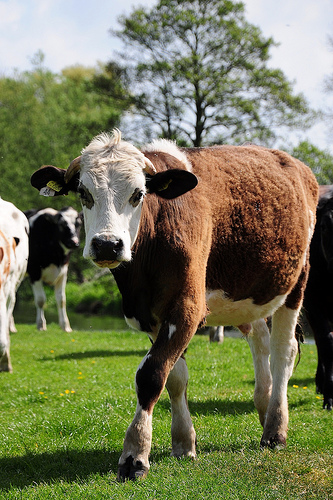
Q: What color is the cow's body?
A: Brown.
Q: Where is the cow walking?
A: On grass.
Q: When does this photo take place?
A: Daytime.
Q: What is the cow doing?
A: Walking.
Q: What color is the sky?
A: Blue.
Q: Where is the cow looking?
A: Straight ahead.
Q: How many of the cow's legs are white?
A: All four.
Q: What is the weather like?
A: Cloudy and sunny.